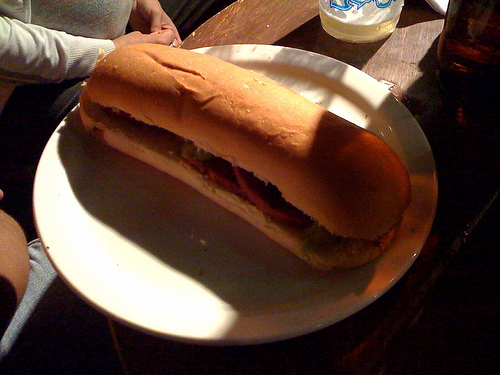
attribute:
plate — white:
[29, 37, 444, 349]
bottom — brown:
[439, 46, 499, 85]